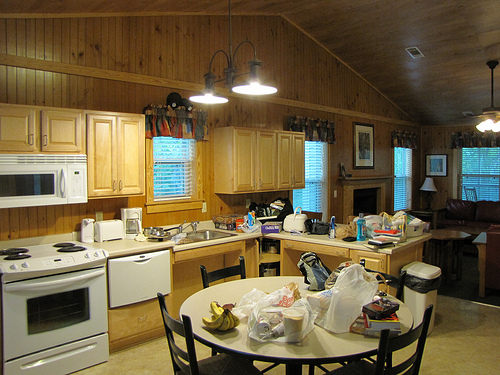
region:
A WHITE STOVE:
[3, 232, 118, 371]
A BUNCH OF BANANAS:
[196, 297, 246, 336]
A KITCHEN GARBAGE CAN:
[394, 257, 451, 334]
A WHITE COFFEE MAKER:
[121, 204, 149, 242]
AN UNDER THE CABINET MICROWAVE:
[2, 152, 91, 207]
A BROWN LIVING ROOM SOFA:
[433, 194, 499, 237]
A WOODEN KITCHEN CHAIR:
[151, 291, 257, 373]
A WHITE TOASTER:
[94, 213, 129, 245]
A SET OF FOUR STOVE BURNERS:
[1, 232, 93, 264]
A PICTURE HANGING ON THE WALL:
[346, 120, 388, 171]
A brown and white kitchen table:
[170, 237, 420, 353]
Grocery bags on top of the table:
[240, 270, 365, 335]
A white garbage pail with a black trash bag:
[400, 255, 450, 331]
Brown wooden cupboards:
[212, 127, 309, 194]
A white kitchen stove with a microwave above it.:
[0, 155, 120, 362]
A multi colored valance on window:
[150, 110, 215, 195]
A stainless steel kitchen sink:
[150, 215, 240, 245]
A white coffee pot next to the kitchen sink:
[121, 200, 148, 240]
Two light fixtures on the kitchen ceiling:
[160, 65, 350, 121]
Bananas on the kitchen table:
[197, 297, 247, 337]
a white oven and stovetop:
[1, 236, 109, 372]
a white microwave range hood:
[0, 152, 90, 212]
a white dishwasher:
[107, 246, 172, 306]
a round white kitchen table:
[182, 264, 414, 370]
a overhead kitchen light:
[187, 7, 273, 110]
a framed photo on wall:
[349, 119, 377, 174]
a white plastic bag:
[312, 254, 373, 335]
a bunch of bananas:
[202, 299, 235, 333]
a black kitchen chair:
[156, 294, 253, 373]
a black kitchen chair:
[336, 308, 434, 373]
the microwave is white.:
[1, 153, 95, 208]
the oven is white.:
[6, 229, 111, 372]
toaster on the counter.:
[94, 217, 127, 241]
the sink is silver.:
[155, 222, 238, 250]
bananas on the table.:
[197, 293, 242, 333]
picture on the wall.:
[340, 116, 379, 173]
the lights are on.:
[182, 67, 272, 111]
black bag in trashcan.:
[399, 270, 443, 294]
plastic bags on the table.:
[232, 250, 399, 340]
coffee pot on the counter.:
[120, 206, 147, 244]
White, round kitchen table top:
[180, 273, 413, 360]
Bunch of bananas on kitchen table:
[200, 295, 240, 335]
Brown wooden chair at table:
[151, 287, 262, 372]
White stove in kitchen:
[0, 236, 110, 371]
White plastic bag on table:
[317, 263, 378, 334]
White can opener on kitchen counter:
[77, 215, 97, 245]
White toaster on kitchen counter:
[93, 216, 124, 242]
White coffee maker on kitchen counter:
[118, 205, 143, 236]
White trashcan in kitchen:
[398, 257, 441, 339]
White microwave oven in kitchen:
[0, 150, 90, 207]